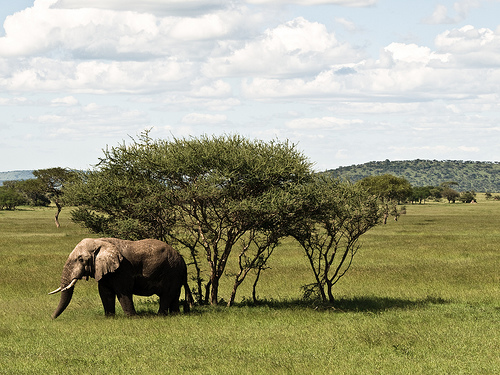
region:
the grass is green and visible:
[287, 246, 397, 355]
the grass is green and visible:
[264, 253, 339, 354]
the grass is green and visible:
[236, 200, 318, 349]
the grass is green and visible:
[245, 285, 293, 360]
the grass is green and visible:
[291, 324, 327, 364]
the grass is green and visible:
[323, 270, 366, 356]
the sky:
[232, 52, 419, 182]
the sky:
[244, 29, 356, 168]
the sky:
[253, 50, 323, 145]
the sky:
[224, 74, 313, 174]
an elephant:
[48, 234, 203, 322]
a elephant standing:
[43, 232, 201, 322]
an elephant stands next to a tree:
[43, 134, 410, 323]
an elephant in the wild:
[40, 234, 215, 316]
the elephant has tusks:
[43, 235, 220, 322]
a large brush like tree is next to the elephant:
[57, 128, 364, 305]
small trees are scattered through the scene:
[5, 165, 497, 314]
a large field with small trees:
[5, 191, 498, 373]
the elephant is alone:
[43, 231, 205, 326]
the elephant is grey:
[42, 233, 223, 325]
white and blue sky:
[31, 11, 306, 116]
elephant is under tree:
[65, 224, 206, 349]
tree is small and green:
[101, 145, 369, 327]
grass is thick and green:
[174, 296, 460, 363]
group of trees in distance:
[343, 156, 420, 213]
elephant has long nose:
[53, 228, 88, 323]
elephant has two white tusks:
[40, 267, 80, 299]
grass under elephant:
[118, 303, 167, 348]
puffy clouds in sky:
[48, 0, 155, 98]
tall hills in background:
[3, 168, 44, 198]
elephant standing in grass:
[26, 222, 202, 329]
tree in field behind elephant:
[57, 130, 312, 321]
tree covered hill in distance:
[285, 140, 499, 212]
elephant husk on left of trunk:
[61, 273, 81, 296]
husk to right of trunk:
[43, 281, 63, 301]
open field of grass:
[1, 196, 497, 373]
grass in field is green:
[6, 200, 499, 374]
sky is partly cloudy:
[1, 3, 499, 183]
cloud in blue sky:
[3, 7, 268, 59]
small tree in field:
[36, 166, 83, 238]